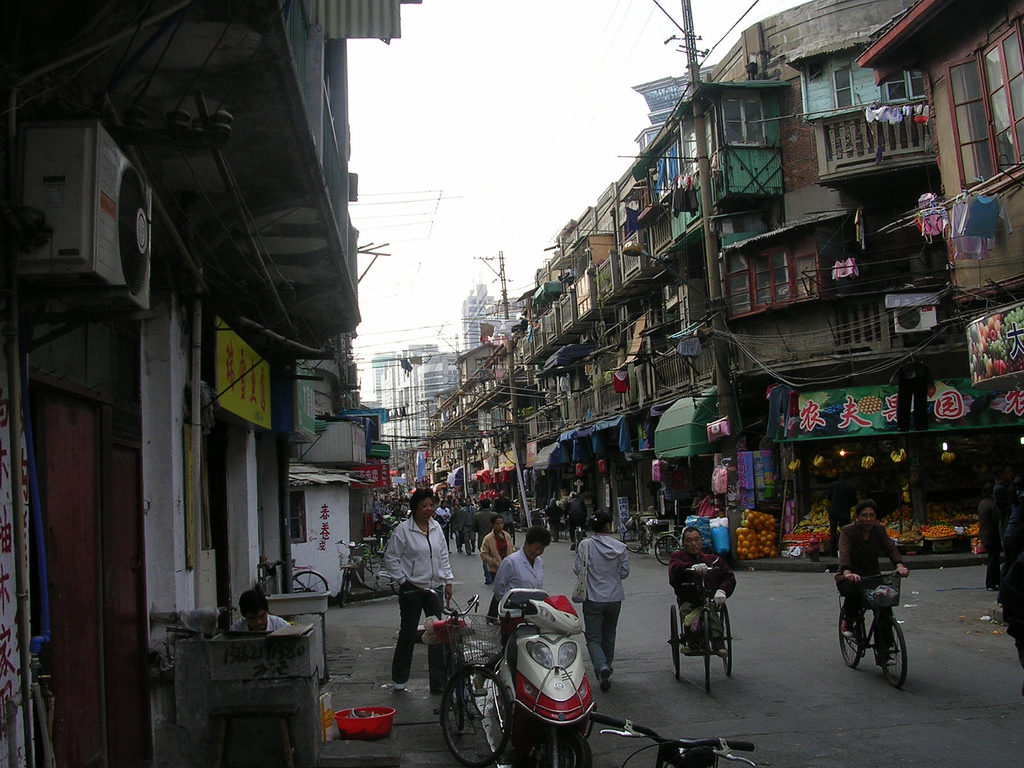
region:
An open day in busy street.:
[0, 0, 1023, 767]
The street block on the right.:
[372, 0, 1022, 567]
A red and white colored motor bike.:
[493, 589, 593, 766]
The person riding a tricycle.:
[662, 520, 742, 691]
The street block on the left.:
[0, 3, 394, 765]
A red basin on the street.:
[341, 703, 395, 735]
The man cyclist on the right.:
[836, 496, 913, 686]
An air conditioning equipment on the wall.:
[21, 112, 157, 318]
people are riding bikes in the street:
[639, 466, 946, 702]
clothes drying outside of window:
[825, 156, 999, 275]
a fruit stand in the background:
[731, 428, 982, 569]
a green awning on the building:
[630, 361, 745, 497]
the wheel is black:
[416, 643, 518, 757]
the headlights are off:
[484, 611, 609, 675]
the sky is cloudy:
[314, 117, 599, 337]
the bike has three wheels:
[653, 504, 774, 714]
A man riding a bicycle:
[816, 484, 921, 697]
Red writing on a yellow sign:
[203, 299, 283, 439]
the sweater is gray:
[586, 535, 637, 602]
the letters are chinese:
[797, 389, 984, 435]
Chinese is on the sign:
[791, 384, 956, 446]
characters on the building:
[307, 492, 349, 563]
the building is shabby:
[286, 463, 364, 581]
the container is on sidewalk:
[340, 696, 410, 748]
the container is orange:
[334, 691, 418, 752]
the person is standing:
[393, 501, 466, 685]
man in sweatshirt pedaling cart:
[653, 508, 755, 680]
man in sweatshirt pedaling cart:
[652, 511, 763, 690]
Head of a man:
[234, 587, 274, 636]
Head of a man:
[403, 481, 443, 529]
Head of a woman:
[489, 506, 508, 539]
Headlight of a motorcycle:
[525, 635, 554, 673]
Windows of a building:
[751, 253, 791, 299]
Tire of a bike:
[874, 604, 914, 694]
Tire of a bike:
[435, 655, 513, 758]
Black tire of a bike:
[429, 655, 516, 766]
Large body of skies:
[468, 81, 568, 164]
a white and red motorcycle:
[505, 597, 579, 744]